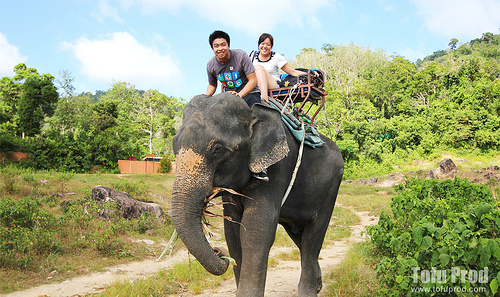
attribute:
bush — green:
[358, 176, 498, 295]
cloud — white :
[67, 27, 184, 89]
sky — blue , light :
[15, 4, 496, 92]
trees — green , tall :
[344, 37, 496, 160]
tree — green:
[17, 58, 126, 173]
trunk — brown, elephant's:
[168, 162, 230, 274]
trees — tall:
[291, 30, 499, 175]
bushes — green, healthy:
[343, 173, 498, 292]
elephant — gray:
[163, 84, 353, 294]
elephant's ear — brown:
[240, 94, 297, 181]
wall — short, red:
[78, 141, 257, 168]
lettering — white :
[403, 287, 490, 294]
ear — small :
[249, 102, 294, 179]